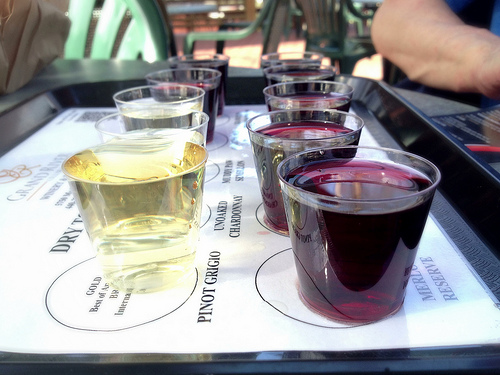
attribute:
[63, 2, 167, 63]
chair — green 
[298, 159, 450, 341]
wine — red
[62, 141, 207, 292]
wine — gold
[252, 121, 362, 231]
wine — red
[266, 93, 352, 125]
wine — red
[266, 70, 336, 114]
wine — red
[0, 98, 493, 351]
mat — white